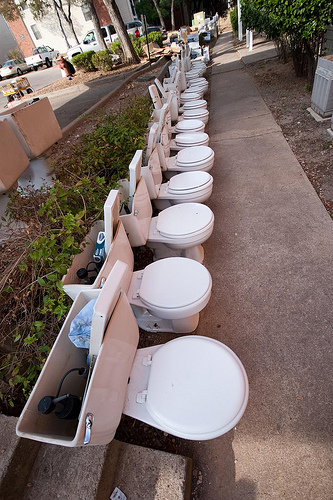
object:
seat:
[103, 188, 213, 334]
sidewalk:
[219, 68, 273, 186]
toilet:
[104, 188, 214, 266]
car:
[67, 25, 113, 67]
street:
[0, 71, 74, 113]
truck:
[105, 19, 145, 37]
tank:
[14, 260, 141, 449]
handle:
[83, 415, 93, 447]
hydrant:
[59, 54, 77, 78]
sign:
[177, 26, 188, 45]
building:
[0, 0, 61, 79]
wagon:
[0, 56, 28, 81]